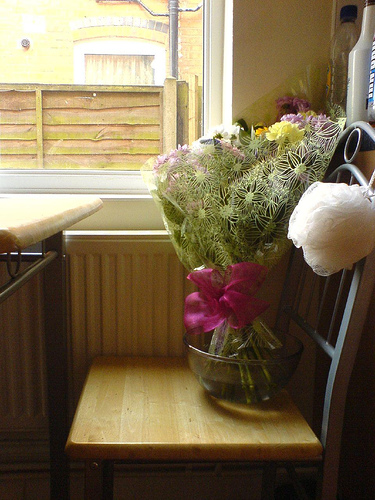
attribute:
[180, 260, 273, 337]
decorative bow — pink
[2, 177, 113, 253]
table top — wooden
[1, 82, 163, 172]
wall — slatted, thin, white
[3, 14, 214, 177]
building — yellow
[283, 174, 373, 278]
sponge — shower , mesh, white 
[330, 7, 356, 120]
bottle — clear 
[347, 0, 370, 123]
bottle — clear 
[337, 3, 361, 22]
cap — bottle , black  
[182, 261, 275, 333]
ribbon — pink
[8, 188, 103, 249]
counter — white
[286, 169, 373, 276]
shower poof — white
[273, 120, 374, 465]
chair back — silver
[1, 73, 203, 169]
wall — slatted , wood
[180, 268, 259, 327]
bow — pink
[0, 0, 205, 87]
wall — rough, wooden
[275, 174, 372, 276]
object — white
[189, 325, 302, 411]
bowl — clear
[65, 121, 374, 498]
chair — wooden 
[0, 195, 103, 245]
tabletop — wooden, brown 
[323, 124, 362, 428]
back — metal